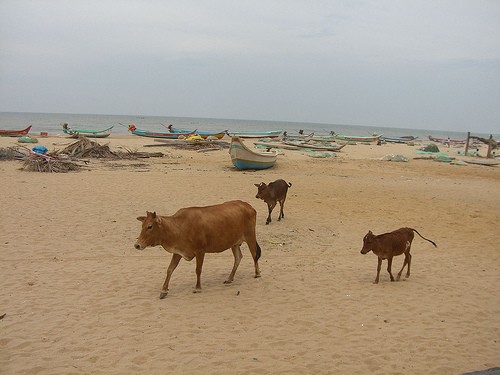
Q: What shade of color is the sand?
A: Brown.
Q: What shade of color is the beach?
A: Brown.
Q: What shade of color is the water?
A: Blue.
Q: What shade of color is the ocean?
A: Blue.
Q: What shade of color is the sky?
A: Gray.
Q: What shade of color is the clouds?
A: Gray.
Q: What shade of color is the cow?
A: Brown.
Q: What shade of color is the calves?
A: Brown.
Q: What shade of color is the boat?
A: Blue.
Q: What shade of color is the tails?
A: Brown.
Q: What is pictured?
A: Animals.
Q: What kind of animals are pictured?
A: Two calves and one cow.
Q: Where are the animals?
A: On a beach.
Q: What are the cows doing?
A: Walking.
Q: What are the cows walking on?
A: Sand.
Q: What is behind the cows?
A: Boats.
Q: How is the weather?
A: Cloudy.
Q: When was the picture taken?
A: During day hours.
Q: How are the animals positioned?
A: Adult cow in front and calves following.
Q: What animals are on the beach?
A: Cows.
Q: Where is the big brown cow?
A: On a beach.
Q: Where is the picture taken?
A: A beach.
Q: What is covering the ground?
A: Sand.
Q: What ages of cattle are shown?
A: Baby and adult.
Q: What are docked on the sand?
A: Boats.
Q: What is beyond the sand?
A: Water.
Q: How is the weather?
A: Overcast.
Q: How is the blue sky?
A: Cloudy.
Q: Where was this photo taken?
A: Beach.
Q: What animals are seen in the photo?
A: Cows.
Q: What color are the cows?
A: Brown.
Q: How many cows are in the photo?
A: Three.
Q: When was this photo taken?
A: Daytime.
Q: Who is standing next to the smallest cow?
A: No one.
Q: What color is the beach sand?
A: Tan.